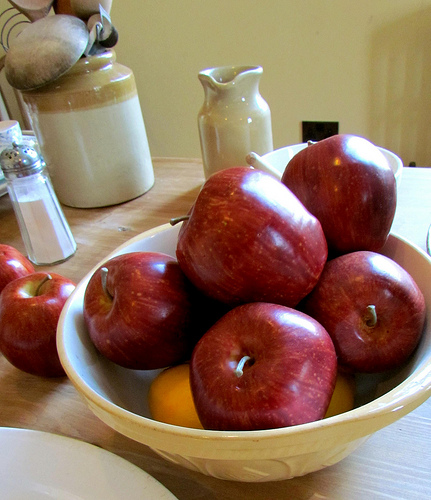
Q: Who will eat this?
A: Man.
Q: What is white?
A: Salt.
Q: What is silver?
A: Salt shaker top.